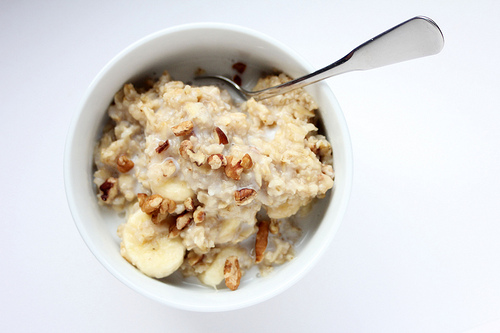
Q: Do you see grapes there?
A: No, there are no grapes.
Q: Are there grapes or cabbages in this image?
A: No, there are no grapes or cabbages.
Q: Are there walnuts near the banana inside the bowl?
A: Yes, there is a walnut near the banana.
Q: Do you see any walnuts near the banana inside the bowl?
A: Yes, there is a walnut near the banana.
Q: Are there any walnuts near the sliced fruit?
A: Yes, there is a walnut near the banana.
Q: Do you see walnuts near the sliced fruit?
A: Yes, there is a walnut near the banana.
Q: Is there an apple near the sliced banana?
A: No, there is a walnut near the banana.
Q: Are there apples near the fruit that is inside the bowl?
A: No, there is a walnut near the banana.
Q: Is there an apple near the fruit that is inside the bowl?
A: No, there is a walnut near the banana.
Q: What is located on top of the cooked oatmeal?
A: The walnut is on top of the oatmeal.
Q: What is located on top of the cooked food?
A: The walnut is on top of the oatmeal.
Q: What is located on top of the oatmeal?
A: The walnut is on top of the oatmeal.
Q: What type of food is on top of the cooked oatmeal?
A: The food is a walnut.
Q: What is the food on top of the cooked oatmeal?
A: The food is a walnut.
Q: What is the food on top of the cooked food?
A: The food is a walnut.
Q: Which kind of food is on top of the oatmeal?
A: The food is a walnut.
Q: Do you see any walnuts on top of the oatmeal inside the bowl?
A: Yes, there is a walnut on top of the oatmeal.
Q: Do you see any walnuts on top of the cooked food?
A: Yes, there is a walnut on top of the oatmeal.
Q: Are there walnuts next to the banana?
A: Yes, there is a walnut next to the banana.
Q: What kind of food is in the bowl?
A: The food is a walnut.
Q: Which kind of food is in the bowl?
A: The food is a walnut.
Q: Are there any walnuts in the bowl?
A: Yes, there is a walnut in the bowl.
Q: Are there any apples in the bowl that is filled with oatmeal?
A: No, there is a walnut in the bowl.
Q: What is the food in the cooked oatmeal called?
A: The food is a walnut.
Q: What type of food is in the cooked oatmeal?
A: The food is a walnut.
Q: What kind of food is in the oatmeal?
A: The food is a walnut.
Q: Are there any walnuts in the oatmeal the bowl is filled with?
A: Yes, there is a walnut in the oatmeal.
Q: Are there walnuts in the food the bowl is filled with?
A: Yes, there is a walnut in the oatmeal.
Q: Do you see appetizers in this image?
A: No, there are no appetizers.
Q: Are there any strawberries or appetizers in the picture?
A: No, there are no appetizers or strawberries.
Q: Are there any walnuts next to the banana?
A: Yes, there is a walnut next to the banana.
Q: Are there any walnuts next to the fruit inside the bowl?
A: Yes, there is a walnut next to the banana.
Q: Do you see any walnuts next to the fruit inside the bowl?
A: Yes, there is a walnut next to the banana.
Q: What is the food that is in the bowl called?
A: The food is a walnut.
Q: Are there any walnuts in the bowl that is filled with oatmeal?
A: Yes, there is a walnut in the bowl.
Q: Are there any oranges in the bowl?
A: No, there is a walnut in the bowl.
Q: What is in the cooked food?
A: The walnut is in the oatmeal.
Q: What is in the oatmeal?
A: The walnut is in the oatmeal.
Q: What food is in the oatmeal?
A: The food is a walnut.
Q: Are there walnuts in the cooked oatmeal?
A: Yes, there is a walnut in the oatmeal.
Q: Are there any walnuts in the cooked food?
A: Yes, there is a walnut in the oatmeal.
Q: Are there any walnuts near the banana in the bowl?
A: Yes, there is a walnut near the banana.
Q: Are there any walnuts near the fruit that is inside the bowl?
A: Yes, there is a walnut near the banana.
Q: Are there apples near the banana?
A: No, there is a walnut near the banana.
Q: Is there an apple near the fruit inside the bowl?
A: No, there is a walnut near the banana.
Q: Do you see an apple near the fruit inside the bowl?
A: No, there is a walnut near the banana.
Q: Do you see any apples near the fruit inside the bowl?
A: No, there is a walnut near the banana.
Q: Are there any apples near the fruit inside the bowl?
A: No, there is a walnut near the banana.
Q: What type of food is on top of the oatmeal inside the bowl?
A: The food is a walnut.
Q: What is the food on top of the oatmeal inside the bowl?
A: The food is a walnut.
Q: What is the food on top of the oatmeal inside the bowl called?
A: The food is a walnut.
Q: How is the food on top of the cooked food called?
A: The food is a walnut.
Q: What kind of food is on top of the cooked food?
A: The food is a walnut.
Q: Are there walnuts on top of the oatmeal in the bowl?
A: Yes, there is a walnut on top of the oatmeal.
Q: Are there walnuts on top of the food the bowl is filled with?
A: Yes, there is a walnut on top of the oatmeal.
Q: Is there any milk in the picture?
A: Yes, there is milk.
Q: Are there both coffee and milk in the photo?
A: No, there is milk but no coffee.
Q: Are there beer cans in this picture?
A: No, there are no beer cans.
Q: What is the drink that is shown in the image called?
A: The drink is milk.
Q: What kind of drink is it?
A: The drink is milk.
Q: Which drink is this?
A: This is milk.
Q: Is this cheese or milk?
A: This is milk.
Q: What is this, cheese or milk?
A: This is milk.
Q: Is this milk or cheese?
A: This is milk.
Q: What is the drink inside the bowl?
A: The drink is milk.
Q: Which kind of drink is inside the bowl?
A: The drink is milk.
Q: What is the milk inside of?
A: The milk is inside the bowl.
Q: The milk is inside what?
A: The milk is inside the bowl.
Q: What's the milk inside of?
A: The milk is inside the bowl.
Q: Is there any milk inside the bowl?
A: Yes, there is milk inside the bowl.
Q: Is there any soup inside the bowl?
A: No, there is milk inside the bowl.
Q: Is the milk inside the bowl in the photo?
A: Yes, the milk is inside the bowl.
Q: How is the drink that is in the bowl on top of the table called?
A: The drink is milk.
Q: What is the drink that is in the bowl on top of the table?
A: The drink is milk.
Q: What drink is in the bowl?
A: The drink is milk.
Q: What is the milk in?
A: The milk is in the bowl.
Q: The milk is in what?
A: The milk is in the bowl.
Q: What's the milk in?
A: The milk is in the bowl.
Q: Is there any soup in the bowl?
A: No, there is milk in the bowl.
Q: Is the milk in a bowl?
A: Yes, the milk is in a bowl.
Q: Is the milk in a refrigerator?
A: No, the milk is in a bowl.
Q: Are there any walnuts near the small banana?
A: Yes, there is a walnut near the banana.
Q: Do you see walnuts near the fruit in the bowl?
A: Yes, there is a walnut near the banana.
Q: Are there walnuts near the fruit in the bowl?
A: Yes, there is a walnut near the banana.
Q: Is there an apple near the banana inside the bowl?
A: No, there is a walnut near the banana.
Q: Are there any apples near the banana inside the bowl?
A: No, there is a walnut near the banana.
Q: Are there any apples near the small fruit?
A: No, there is a walnut near the banana.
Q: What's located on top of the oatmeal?
A: The walnut is on top of the oatmeal.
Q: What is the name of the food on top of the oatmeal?
A: The food is a walnut.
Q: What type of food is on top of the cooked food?
A: The food is a walnut.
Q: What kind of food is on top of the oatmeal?
A: The food is a walnut.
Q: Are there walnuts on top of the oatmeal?
A: Yes, there is a walnut on top of the oatmeal.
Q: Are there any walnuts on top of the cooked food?
A: Yes, there is a walnut on top of the oatmeal.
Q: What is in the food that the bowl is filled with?
A: The walnut is in the oatmeal.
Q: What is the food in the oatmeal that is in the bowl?
A: The food is a walnut.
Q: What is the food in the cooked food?
A: The food is a walnut.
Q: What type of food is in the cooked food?
A: The food is a walnut.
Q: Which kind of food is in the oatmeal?
A: The food is a walnut.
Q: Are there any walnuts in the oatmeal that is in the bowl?
A: Yes, there is a walnut in the oatmeal.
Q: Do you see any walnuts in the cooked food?
A: Yes, there is a walnut in the oatmeal.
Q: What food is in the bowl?
A: The food is a walnut.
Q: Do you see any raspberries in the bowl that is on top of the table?
A: No, there is a walnut in the bowl.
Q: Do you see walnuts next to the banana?
A: Yes, there is a walnut next to the banana.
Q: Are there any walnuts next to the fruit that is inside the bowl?
A: Yes, there is a walnut next to the banana.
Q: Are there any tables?
A: Yes, there is a table.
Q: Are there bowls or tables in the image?
A: Yes, there is a table.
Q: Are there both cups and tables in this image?
A: No, there is a table but no cups.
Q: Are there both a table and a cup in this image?
A: No, there is a table but no cups.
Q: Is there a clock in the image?
A: No, there are no clocks.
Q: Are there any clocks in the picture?
A: No, there are no clocks.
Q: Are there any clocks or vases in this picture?
A: No, there are no clocks or vases.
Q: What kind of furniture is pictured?
A: The furniture is a table.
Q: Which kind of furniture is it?
A: The piece of furniture is a table.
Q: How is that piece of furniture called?
A: This is a table.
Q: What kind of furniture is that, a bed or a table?
A: This is a table.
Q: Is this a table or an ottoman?
A: This is a table.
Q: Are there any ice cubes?
A: No, there are no ice cubes.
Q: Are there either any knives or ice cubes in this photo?
A: No, there are no ice cubes or knives.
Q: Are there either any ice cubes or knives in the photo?
A: No, there are no ice cubes or knives.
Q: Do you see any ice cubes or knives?
A: No, there are no ice cubes or knives.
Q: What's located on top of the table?
A: The bowl is on top of the table.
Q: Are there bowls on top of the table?
A: Yes, there is a bowl on top of the table.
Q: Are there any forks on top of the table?
A: No, there is a bowl on top of the table.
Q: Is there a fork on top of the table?
A: No, there is a bowl on top of the table.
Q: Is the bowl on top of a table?
A: Yes, the bowl is on top of a table.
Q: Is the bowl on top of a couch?
A: No, the bowl is on top of a table.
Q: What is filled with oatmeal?
A: The bowl is filled with oatmeal.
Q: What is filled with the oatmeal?
A: The bowl is filled with oatmeal.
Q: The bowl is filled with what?
A: The bowl is filled with oatmeal.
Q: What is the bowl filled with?
A: The bowl is filled with oatmeal.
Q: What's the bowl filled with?
A: The bowl is filled with oatmeal.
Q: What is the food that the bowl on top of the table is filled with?
A: The food is oatmeal.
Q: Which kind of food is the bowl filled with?
A: The bowl is filled with oatmeal.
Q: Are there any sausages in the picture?
A: No, there are no sausages.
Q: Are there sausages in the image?
A: No, there are no sausages.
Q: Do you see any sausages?
A: No, there are no sausages.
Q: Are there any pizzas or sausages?
A: No, there are no sausages or pizzas.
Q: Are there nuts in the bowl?
A: Yes, there is a nut in the bowl.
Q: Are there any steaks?
A: No, there are no steaks.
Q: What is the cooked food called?
A: The food is oatmeal.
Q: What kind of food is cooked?
A: The food is oatmeal.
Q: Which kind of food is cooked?
A: The food is oatmeal.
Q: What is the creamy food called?
A: The food is oatmeal.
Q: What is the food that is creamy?
A: The food is oatmeal.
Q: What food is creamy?
A: The food is oatmeal.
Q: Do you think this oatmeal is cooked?
A: Yes, the oatmeal is cooked.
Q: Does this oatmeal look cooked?
A: Yes, the oatmeal is cooked.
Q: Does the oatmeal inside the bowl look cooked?
A: Yes, the oatmeal is cooked.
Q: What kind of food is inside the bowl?
A: The food is oatmeal.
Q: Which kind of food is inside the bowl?
A: The food is oatmeal.